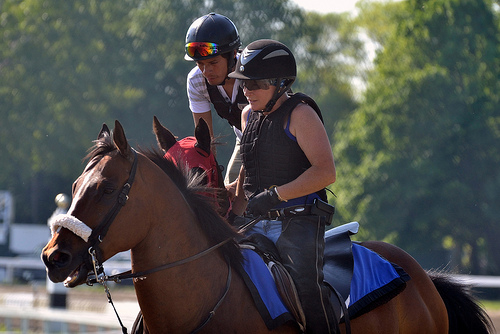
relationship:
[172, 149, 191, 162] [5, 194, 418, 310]
mask on horse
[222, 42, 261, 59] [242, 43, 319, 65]
logo on helmet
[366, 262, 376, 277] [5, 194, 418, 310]
blanket on horse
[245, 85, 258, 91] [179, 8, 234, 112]
shades on man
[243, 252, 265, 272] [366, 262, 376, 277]
saddle on blanket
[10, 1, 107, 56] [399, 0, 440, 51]
leaves on trees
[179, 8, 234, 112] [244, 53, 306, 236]
man behind woman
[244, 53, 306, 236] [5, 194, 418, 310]
woman on horse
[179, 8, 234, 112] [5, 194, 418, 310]
man on horse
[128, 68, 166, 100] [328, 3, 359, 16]
sky between branches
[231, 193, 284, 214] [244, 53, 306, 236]
gloves on woman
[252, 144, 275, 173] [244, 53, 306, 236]
vest on woman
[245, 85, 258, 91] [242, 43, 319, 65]
shades on helmet